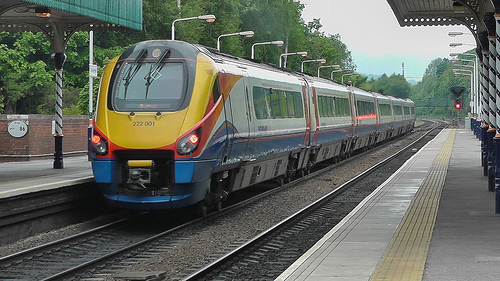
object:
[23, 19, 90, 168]
pole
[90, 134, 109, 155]
headlights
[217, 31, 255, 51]
lights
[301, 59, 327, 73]
light pole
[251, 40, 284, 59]
light pole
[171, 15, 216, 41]
light pole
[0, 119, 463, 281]
railway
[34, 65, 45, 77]
leaf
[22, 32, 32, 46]
leaf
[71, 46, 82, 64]
leaf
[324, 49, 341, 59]
leaf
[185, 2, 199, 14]
leaf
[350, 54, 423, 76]
blue sky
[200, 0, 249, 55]
tree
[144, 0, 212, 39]
tree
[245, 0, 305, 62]
tree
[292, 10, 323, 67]
tree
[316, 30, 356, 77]
tree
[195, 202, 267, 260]
rocks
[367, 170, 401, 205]
ground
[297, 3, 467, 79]
sky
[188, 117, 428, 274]
metal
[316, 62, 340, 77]
pole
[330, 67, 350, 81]
pole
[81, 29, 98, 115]
pole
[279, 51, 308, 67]
pole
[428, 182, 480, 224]
floor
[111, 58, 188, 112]
windscreen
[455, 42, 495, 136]
pole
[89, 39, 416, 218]
train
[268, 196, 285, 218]
ballast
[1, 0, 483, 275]
photo